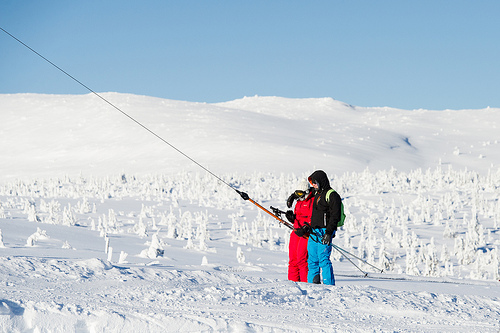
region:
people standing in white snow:
[270, 161, 348, 296]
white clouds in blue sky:
[18, 13, 62, 61]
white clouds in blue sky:
[202, 22, 236, 40]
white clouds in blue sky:
[377, 29, 417, 59]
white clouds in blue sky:
[318, 19, 373, 96]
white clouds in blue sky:
[232, 26, 274, 81]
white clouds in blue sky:
[182, 19, 249, 89]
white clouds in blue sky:
[134, 32, 182, 67]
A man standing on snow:
[297, 169, 354, 279]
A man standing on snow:
[269, 181, 313, 272]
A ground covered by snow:
[360, 274, 469, 331]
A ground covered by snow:
[138, 278, 270, 329]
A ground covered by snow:
[7, 200, 124, 330]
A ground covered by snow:
[395, 163, 496, 263]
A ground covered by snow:
[87, 125, 206, 200]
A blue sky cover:
[369, 28, 468, 89]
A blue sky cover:
[151, 10, 297, 101]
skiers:
[271, 155, 348, 293]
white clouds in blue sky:
[21, 15, 82, 49]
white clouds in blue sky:
[402, 32, 447, 64]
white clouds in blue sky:
[342, 62, 370, 84]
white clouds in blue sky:
[388, 45, 442, 89]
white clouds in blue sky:
[350, 19, 407, 64]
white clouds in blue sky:
[318, 43, 372, 71]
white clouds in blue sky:
[218, 36, 323, 101]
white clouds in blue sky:
[111, 32, 149, 63]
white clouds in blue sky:
[37, 11, 79, 38]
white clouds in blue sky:
[411, 21, 434, 45]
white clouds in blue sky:
[245, 33, 295, 73]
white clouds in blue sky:
[131, 15, 187, 75]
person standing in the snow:
[305, 162, 346, 287]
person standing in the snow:
[279, 174, 311, 282]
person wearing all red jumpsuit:
[286, 177, 310, 277]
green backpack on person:
[323, 185, 348, 230]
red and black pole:
[234, 184, 295, 241]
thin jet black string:
[0, 27, 238, 195]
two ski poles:
[329, 238, 400, 280]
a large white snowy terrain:
[6, 90, 498, 331]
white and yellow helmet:
[292, 181, 314, 197]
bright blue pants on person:
[309, 226, 334, 286]